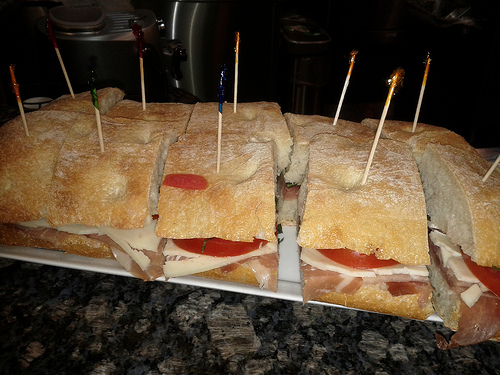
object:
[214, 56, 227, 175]
toothpick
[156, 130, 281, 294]
sub sandwich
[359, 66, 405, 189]
toothpick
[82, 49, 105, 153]
toothpick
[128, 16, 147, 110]
toothpick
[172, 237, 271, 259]
tomato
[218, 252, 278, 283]
meat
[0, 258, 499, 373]
countertop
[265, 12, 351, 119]
side table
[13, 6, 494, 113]
background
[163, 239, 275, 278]
cheese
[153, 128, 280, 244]
bread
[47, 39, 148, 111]
two red toothpicks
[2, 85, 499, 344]
sandwich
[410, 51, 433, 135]
orange toothpicks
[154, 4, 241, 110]
drink dispenser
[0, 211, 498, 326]
serving plate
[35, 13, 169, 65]
meat slicer